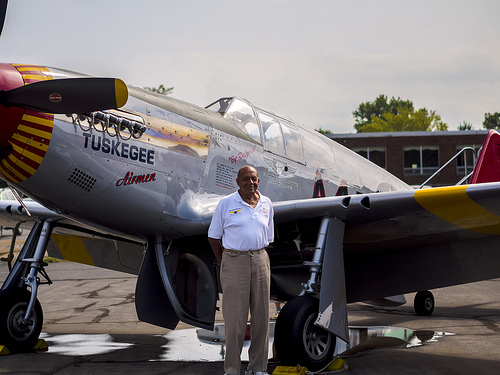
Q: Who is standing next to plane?
A: Man in white shirt.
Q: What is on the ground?
A: Puddle of water.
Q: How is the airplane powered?
A: Propeller.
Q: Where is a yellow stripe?
A: Left wing.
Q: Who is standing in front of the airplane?
A: A man.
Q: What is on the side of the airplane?
A: Name.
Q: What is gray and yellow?
A: Airplane wing.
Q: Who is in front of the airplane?
A: A man.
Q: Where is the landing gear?
A: Front of the airplane.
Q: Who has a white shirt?
A: A man.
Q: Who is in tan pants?
A: A man.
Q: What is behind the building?
A: Tree tops.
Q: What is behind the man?
A: A plane.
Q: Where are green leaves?
A: On trees.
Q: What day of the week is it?
A: Tuesday.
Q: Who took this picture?
A: The pilot.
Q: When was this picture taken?
A: Yesterday.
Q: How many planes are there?
A: One.